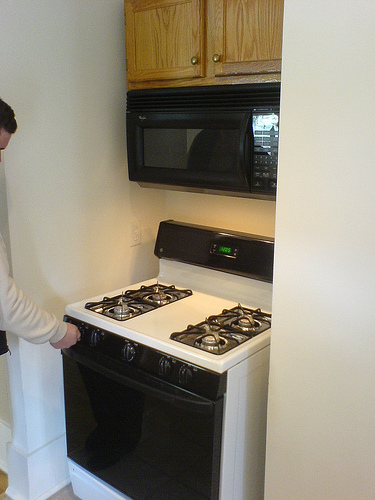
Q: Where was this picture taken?
A: A kitchen.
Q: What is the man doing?
A: Starting the oven.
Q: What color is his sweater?
A: Tan.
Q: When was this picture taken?
A: Daytime.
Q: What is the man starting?
A: The burner.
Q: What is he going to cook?
A: Food.